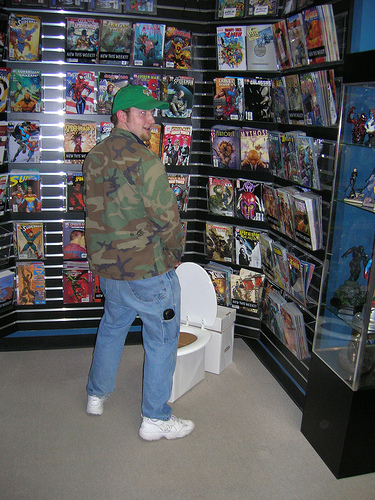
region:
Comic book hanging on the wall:
[58, 64, 96, 118]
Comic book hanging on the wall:
[8, 216, 46, 253]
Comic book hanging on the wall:
[12, 258, 47, 303]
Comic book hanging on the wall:
[51, 249, 96, 309]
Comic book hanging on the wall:
[6, 115, 38, 150]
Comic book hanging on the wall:
[205, 173, 235, 218]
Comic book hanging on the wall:
[213, 74, 244, 124]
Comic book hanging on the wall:
[212, 119, 240, 166]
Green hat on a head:
[70, 74, 169, 135]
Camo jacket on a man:
[64, 124, 193, 288]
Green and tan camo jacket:
[81, 130, 187, 281]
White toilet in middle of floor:
[173, 262, 236, 403]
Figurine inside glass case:
[331, 243, 367, 306]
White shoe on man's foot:
[138, 414, 194, 440]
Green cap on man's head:
[109, 86, 170, 111]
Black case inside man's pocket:
[160, 307, 175, 320]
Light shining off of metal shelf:
[42, 20, 66, 65]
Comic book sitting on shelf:
[213, 76, 242, 121]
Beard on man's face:
[139, 130, 152, 140]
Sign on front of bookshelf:
[65, 48, 96, 59]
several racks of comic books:
[1, 0, 341, 356]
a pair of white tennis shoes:
[85, 393, 192, 439]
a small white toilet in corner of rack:
[162, 261, 211, 405]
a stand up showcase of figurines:
[301, 59, 373, 477]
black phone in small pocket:
[162, 307, 175, 320]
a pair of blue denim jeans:
[88, 273, 173, 421]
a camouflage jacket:
[81, 128, 182, 281]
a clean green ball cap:
[113, 84, 168, 111]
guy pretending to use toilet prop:
[86, 85, 193, 442]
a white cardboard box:
[208, 306, 234, 372]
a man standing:
[81, 84, 203, 440]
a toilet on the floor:
[140, 257, 235, 403]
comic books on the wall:
[215, 65, 340, 123]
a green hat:
[112, 83, 168, 115]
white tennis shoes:
[135, 412, 197, 436]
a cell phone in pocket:
[166, 307, 179, 342]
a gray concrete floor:
[11, 396, 81, 495]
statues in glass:
[324, 240, 372, 320]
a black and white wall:
[1, 168, 71, 329]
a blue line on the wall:
[9, 322, 96, 345]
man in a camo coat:
[48, 76, 230, 445]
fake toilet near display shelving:
[136, 255, 213, 405]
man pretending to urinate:
[78, 81, 199, 446]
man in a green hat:
[77, 75, 224, 441]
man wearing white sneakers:
[71, 80, 219, 446]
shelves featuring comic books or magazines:
[207, 18, 314, 357]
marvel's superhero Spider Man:
[56, 70, 99, 116]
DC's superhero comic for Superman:
[5, 13, 43, 61]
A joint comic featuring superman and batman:
[4, 121, 39, 166]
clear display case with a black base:
[291, 2, 373, 483]